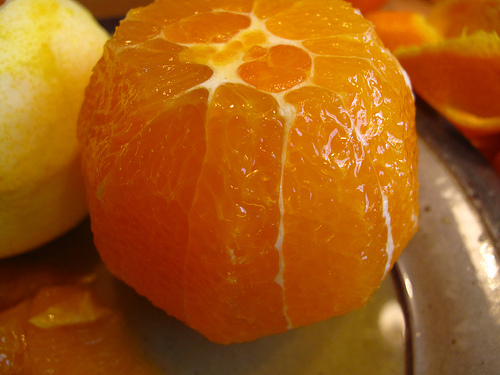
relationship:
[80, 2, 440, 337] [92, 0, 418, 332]
orange has white lines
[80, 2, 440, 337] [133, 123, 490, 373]
orange on plate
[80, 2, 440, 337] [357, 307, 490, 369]
orange on plate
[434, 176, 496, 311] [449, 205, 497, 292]
reflection of light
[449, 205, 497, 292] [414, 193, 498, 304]
light on tray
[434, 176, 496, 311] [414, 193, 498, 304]
reflection on tray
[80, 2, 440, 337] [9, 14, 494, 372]
orange on plate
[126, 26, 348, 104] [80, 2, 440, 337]
top of orange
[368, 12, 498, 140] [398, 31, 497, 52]
rind with pith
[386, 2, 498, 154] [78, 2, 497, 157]
peels in background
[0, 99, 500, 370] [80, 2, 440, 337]
plate under orange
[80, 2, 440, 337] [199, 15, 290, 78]
orange with healthy pith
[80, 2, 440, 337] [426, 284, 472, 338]
orange on plate